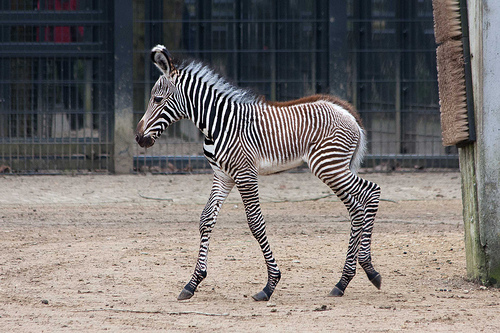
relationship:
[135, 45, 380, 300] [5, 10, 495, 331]
zebra in enclosure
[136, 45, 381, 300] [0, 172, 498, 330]
zebra walking on dirt